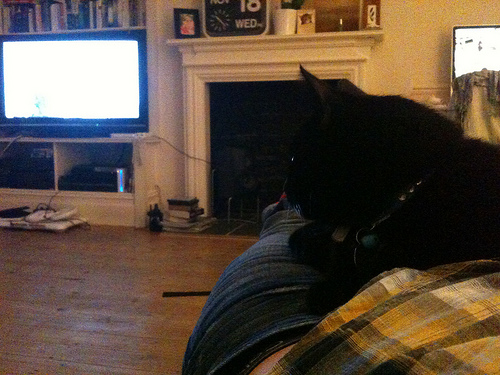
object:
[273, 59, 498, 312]
cat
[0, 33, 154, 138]
television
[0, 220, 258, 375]
floor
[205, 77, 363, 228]
fireplace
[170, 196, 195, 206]
books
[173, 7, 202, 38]
frame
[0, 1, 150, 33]
books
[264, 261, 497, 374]
shirt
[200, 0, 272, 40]
clock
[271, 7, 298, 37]
flower pot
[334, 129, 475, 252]
collar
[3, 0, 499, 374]
room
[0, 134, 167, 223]
stand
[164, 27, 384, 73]
mantle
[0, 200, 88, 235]
items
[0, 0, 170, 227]
bookshelf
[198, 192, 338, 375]
jeans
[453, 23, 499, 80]
window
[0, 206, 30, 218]
remote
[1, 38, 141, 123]
screen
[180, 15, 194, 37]
picture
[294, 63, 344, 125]
ear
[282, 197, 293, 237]
whiskers